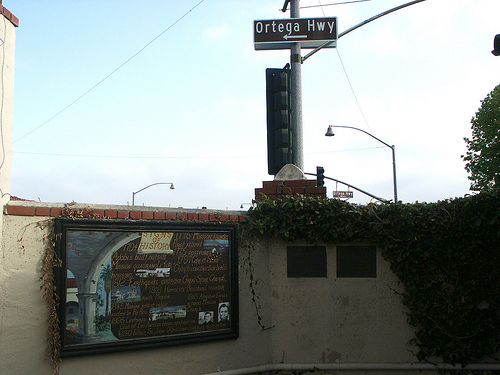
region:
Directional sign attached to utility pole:
[251, 13, 344, 47]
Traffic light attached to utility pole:
[257, 52, 300, 176]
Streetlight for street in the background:
[324, 117, 414, 204]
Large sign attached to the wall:
[53, 216, 241, 349]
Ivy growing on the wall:
[382, 245, 469, 367]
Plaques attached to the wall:
[280, 239, 382, 284]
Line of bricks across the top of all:
[17, 197, 63, 220]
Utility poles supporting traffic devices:
[287, 13, 307, 180]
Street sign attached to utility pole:
[329, 185, 354, 197]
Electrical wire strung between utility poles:
[62, 17, 177, 125]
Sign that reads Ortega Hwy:
[248, 10, 345, 50]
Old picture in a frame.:
[44, 216, 252, 357]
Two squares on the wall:
[276, 242, 391, 282]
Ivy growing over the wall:
[384, 193, 499, 345]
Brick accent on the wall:
[8, 188, 249, 223]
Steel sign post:
[286, 42, 311, 174]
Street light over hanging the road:
[321, 115, 401, 172]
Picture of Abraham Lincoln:
[215, 296, 233, 327]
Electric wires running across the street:
[39, 7, 200, 97]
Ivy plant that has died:
[18, 214, 58, 371]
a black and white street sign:
[250, 18, 340, 50]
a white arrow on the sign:
[282, 31, 303, 41]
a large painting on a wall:
[50, 212, 238, 356]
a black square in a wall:
[283, 243, 326, 280]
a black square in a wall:
[335, 241, 384, 279]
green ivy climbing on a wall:
[252, 195, 495, 374]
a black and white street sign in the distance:
[329, 187, 352, 201]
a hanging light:
[166, 178, 178, 193]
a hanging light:
[325, 126, 337, 138]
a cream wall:
[2, 201, 273, 373]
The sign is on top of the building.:
[225, 11, 371, 71]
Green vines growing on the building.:
[373, 201, 492, 350]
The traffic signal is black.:
[241, 56, 318, 169]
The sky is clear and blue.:
[39, 31, 444, 169]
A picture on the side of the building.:
[48, 216, 262, 353]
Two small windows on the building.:
[257, 226, 392, 302]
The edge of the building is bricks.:
[6, 206, 261, 233]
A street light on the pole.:
[325, 113, 420, 206]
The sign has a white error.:
[271, 30, 315, 47]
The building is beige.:
[278, 279, 425, 365]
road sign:
[221, 17, 349, 94]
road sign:
[255, 1, 387, 122]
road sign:
[246, 13, 371, 73]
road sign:
[260, 0, 350, 50]